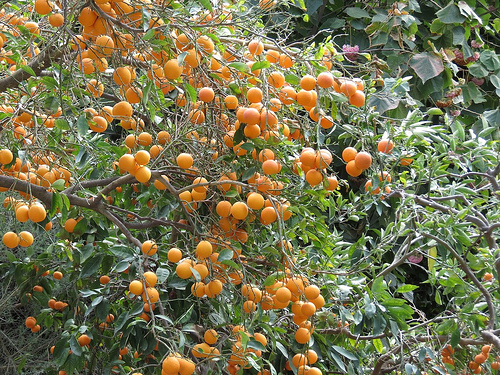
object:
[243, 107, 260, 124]
peach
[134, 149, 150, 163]
peach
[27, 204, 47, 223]
peach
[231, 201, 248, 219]
peach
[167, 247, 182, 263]
peach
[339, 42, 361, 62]
purple leaf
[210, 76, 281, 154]
orange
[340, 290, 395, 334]
leaves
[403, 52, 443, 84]
leaf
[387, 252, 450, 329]
hole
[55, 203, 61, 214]
brown spot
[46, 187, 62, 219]
leaf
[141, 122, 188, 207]
vine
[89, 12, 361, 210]
orange fruits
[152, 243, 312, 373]
orange fruits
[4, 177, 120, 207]
branche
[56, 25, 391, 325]
stuff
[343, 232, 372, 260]
leaf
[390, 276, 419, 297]
leaf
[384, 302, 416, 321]
leaf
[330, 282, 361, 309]
leaf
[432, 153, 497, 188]
branch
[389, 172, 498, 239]
branch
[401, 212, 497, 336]
branch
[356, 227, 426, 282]
branch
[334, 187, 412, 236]
branch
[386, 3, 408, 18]
brown leaves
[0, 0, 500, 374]
bush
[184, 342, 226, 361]
leaf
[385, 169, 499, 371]
green/leafy branches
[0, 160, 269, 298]
green/leafy branches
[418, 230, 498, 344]
brown stick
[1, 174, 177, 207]
brown stick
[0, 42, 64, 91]
brown stick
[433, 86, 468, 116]
dead blossoms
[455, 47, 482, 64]
dead blossoms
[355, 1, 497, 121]
plant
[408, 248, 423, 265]
petal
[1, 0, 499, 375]
oranges/trees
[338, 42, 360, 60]
blossom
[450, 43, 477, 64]
blossom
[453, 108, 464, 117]
blossom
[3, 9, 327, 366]
oranges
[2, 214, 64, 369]
branch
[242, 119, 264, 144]
oranges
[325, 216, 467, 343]
leaves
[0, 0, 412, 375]
yellow fruits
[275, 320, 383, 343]
vine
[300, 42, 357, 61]
vine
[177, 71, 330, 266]
oranges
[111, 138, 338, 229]
branch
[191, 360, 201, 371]
date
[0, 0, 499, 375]
background